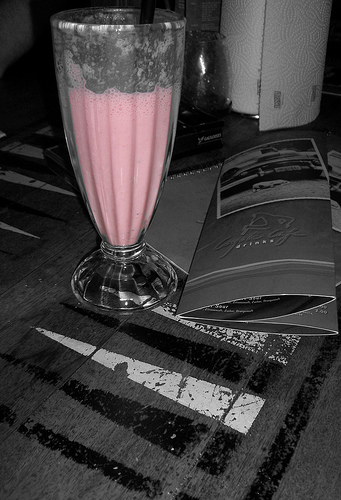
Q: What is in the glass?
A: A shake.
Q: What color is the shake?
A: Pink.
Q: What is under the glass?
A: A table.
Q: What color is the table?
A: Black.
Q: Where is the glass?
A: On the table.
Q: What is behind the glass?
A: Paper towels.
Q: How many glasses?
A: 1.